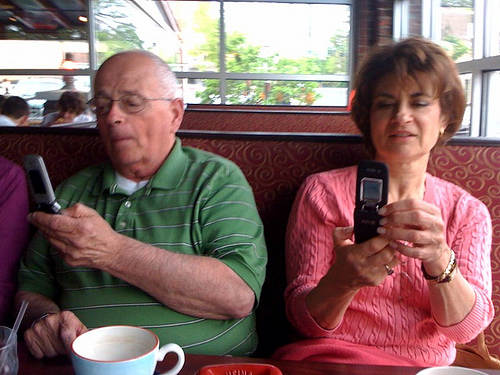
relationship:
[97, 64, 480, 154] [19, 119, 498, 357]
couple seated in restaurant booth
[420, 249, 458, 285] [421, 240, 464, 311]
bracelet on wrist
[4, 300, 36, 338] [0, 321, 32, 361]
straw resting on rim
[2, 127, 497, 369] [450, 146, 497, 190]
bench has design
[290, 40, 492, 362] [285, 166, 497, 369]
lady wearing sweater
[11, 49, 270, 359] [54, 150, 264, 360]
man wearing shirt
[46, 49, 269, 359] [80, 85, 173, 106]
man wearing glasses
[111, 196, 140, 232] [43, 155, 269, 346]
buttons are attached to shirt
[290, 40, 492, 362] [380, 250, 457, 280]
lady wearing jewelry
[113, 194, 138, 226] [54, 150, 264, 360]
buttons are attached to shirt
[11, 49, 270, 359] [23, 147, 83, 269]
man looking at phone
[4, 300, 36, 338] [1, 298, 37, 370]
straw inside glass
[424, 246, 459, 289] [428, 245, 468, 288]
bracelet encircling wrist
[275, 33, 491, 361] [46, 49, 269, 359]
lady sitting man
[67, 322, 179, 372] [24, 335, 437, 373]
mug on top of table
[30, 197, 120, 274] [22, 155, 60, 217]
hand holding phone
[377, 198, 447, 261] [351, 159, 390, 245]
hand holding phone